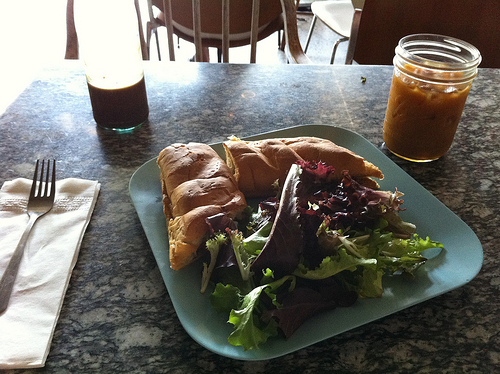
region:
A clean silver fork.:
[0, 144, 64, 310]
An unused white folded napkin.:
[4, 165, 89, 363]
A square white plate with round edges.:
[116, 128, 491, 355]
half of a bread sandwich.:
[153, 138, 240, 261]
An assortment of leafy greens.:
[189, 163, 429, 346]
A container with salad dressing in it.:
[58, 0, 158, 133]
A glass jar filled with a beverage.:
[377, 22, 491, 164]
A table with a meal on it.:
[54, 62, 471, 369]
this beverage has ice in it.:
[369, 28, 489, 158]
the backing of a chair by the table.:
[106, 0, 323, 65]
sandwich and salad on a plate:
[127, 123, 482, 355]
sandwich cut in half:
[157, 135, 382, 270]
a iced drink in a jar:
[381, 34, 478, 166]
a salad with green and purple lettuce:
[200, 170, 445, 347]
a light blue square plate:
[132, 118, 482, 352]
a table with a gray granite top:
[10, 65, 497, 372]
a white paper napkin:
[1, 180, 89, 370]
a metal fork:
[7, 159, 55, 318]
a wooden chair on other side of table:
[67, 3, 311, 65]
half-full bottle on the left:
[77, 3, 151, 132]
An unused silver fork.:
[5, 145, 95, 355]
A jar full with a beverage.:
[381, 15, 478, 183]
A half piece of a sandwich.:
[145, 135, 244, 257]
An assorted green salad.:
[195, 185, 477, 300]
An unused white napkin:
[6, 151, 88, 372]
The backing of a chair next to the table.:
[121, 0, 338, 65]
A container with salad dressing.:
[62, 6, 162, 131]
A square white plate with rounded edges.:
[119, 128, 484, 363]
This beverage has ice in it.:
[380, 26, 479, 190]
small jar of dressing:
[380, 45, 478, 172]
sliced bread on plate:
[159, 135, 316, 253]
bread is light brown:
[136, 123, 357, 263]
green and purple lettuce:
[212, 200, 429, 288]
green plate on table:
[142, 139, 482, 319]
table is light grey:
[92, 170, 158, 353]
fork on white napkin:
[4, 152, 59, 312]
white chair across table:
[139, 4, 308, 77]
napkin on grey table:
[9, 172, 104, 354]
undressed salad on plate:
[159, 177, 452, 319]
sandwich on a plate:
[160, 140, 210, 248]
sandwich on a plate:
[231, 140, 367, 171]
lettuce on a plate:
[258, 161, 308, 311]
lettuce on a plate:
[315, 213, 455, 259]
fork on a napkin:
[20, 155, 56, 267]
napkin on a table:
[55, 177, 72, 322]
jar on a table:
[391, 26, 497, 162]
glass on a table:
[68, 17, 168, 143]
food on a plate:
[165, 136, 453, 338]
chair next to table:
[180, 17, 302, 59]